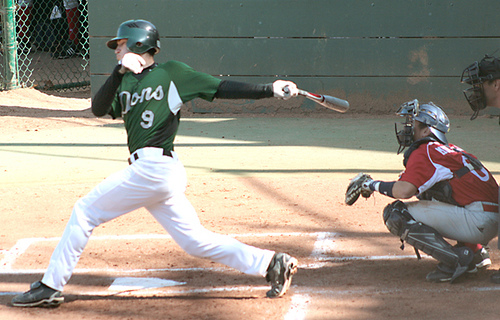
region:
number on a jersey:
[129, 103, 162, 135]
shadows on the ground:
[0, 249, 385, 313]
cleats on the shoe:
[284, 259, 301, 281]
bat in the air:
[291, 83, 357, 119]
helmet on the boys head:
[388, 87, 455, 152]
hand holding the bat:
[262, 76, 307, 108]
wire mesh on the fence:
[17, 44, 83, 86]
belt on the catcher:
[472, 196, 497, 222]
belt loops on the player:
[116, 142, 177, 165]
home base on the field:
[88, 269, 192, 316]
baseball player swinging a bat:
[34, 14, 346, 319]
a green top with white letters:
[89, 53, 221, 161]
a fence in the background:
[15, 0, 106, 101]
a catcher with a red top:
[386, 103, 497, 286]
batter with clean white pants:
[29, 144, 331, 294]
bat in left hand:
[187, 81, 366, 111]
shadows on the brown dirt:
[218, 113, 367, 191]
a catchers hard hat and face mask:
[391, 90, 461, 150]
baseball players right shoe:
[267, 255, 314, 301]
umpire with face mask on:
[455, 51, 494, 123]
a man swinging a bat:
[18, 19, 349, 308]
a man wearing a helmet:
[392, 98, 452, 154]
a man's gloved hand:
[343, 170, 372, 203]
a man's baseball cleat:
[265, 252, 296, 299]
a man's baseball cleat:
[10, 280, 62, 309]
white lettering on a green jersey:
[120, 81, 162, 113]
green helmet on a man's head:
[102, 18, 159, 66]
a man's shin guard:
[382, 199, 463, 275]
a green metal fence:
[2, 0, 87, 96]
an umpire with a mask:
[456, 55, 498, 117]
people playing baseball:
[11, 8, 496, 314]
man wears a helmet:
[74, 8, 204, 130]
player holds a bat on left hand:
[276, 70, 355, 123]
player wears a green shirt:
[76, 13, 353, 175]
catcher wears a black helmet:
[376, 86, 476, 176]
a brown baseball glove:
[335, 160, 383, 210]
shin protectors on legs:
[375, 193, 485, 283]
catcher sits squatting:
[341, 93, 499, 298]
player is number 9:
[59, 9, 244, 154]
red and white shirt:
[401, 135, 499, 209]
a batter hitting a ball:
[31, 20, 352, 315]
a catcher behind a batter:
[348, 89, 498, 310]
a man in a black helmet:
[93, 15, 170, 65]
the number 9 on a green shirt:
[134, 108, 157, 137]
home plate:
[104, 270, 185, 304]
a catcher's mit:
[348, 173, 375, 212]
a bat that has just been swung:
[288, 87, 353, 127]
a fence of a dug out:
[3, 10, 93, 92]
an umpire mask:
[461, 53, 488, 122]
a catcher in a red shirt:
[338, 95, 494, 289]